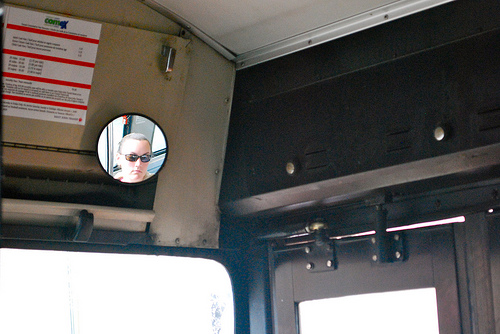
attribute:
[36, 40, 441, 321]
vehicle — here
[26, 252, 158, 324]
window — here, paneled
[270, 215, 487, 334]
door — paneled, metal, hinged, closed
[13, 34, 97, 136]
card — informational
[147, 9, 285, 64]
ceiling — rounded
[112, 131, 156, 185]
person — sitting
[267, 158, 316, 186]
cabinet — metal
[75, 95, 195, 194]
mirror — here, circle, round, bordered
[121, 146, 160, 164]
sunglasses — black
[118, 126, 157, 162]
face — mirror, woman's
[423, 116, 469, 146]
screws — silver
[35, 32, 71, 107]
sign — white, red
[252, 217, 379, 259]
hinge — hydraulic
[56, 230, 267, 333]
windshield — here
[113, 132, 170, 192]
woman — wearing, reflected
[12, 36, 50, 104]
letter — lines